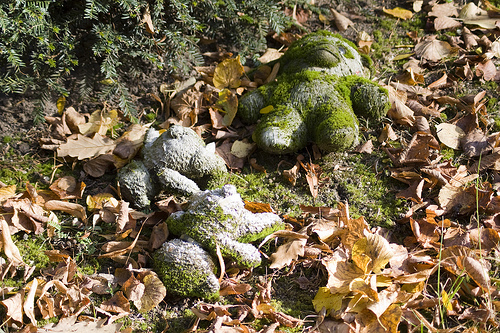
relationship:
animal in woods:
[237, 34, 388, 158] [15, 0, 487, 329]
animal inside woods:
[115, 114, 220, 206] [15, 0, 487, 329]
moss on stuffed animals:
[182, 29, 410, 286] [92, 21, 399, 306]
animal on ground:
[237, 34, 388, 158] [75, 28, 498, 295]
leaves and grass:
[321, 217, 488, 332] [312, 215, 494, 327]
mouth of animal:
[307, 41, 340, 66] [237, 34, 388, 158]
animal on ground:
[237, 34, 388, 158] [2, 0, 499, 331]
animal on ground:
[115, 112, 229, 199] [2, 0, 499, 331]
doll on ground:
[150, 180, 282, 301] [2, 0, 499, 331]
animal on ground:
[115, 114, 220, 206] [2, 0, 499, 331]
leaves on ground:
[4, 7, 498, 328] [2, 0, 499, 331]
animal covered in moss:
[237, 34, 388, 158] [275, 72, 365, 107]